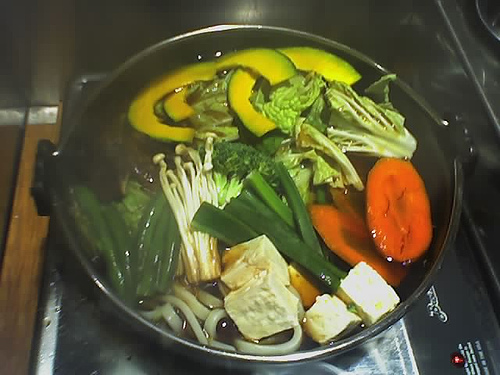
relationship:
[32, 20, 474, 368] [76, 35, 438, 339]
pot of vegetables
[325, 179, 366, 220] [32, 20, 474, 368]
carrot in pot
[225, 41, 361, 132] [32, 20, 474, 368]
avocado in pot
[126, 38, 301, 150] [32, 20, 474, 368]
avocado in pot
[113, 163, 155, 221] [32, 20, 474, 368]
cabbage in pot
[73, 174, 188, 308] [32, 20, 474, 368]
green beans boiled in pot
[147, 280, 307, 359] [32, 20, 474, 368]
noodles in pot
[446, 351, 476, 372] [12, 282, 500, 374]
light on stove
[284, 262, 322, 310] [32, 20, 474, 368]
plantain in pot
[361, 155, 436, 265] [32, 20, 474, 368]
carrot in pot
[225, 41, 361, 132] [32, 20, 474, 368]
avacados in pot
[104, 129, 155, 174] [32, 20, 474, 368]
green peppers in pan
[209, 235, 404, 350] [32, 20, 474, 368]
tofu in pot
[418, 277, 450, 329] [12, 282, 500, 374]
brand os stove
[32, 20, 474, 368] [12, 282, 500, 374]
pot on stove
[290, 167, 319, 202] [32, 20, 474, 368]
onion in pot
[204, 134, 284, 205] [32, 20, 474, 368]
broccoli in pot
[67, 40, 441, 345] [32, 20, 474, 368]
liquid in pot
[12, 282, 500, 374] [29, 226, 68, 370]
stove has white edge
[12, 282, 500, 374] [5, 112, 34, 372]
stove has wood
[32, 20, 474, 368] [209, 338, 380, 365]
pot has shiny edge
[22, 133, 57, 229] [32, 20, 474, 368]
handle on pot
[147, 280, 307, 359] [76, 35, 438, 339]
noodles in broth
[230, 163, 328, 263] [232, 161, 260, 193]
scallions rough edge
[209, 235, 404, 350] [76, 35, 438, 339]
tofu in soup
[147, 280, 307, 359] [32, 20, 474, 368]
noodles in soup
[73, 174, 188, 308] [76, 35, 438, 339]
green beans in soup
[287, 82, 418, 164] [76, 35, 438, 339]
lettuce in soup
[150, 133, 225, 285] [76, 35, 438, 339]
bean sprouts in soup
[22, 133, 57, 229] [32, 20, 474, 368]
handle of pot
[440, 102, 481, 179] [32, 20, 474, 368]
handle of pot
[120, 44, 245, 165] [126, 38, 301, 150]
slice of avocado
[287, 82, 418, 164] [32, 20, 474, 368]
lettuce in pot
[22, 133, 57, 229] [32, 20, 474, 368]
handle in pot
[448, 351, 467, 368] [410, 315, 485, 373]
light on right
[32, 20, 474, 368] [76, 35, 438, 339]
pot of food items